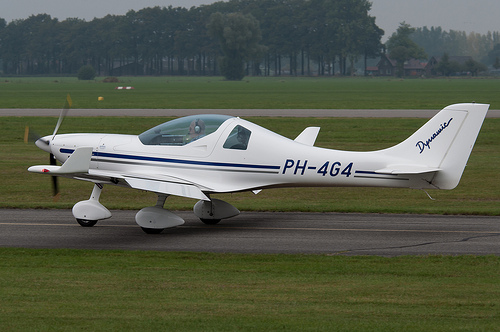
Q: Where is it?
A: This is at the airport.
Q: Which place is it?
A: It is an airport.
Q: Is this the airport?
A: Yes, it is the airport.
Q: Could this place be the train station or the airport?
A: It is the airport.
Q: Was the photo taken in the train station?
A: No, the picture was taken in the airport.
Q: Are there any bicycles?
A: No, there are no bicycles.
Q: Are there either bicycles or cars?
A: No, there are no bicycles or cars.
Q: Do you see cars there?
A: No, there are no cars.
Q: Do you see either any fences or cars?
A: No, there are no cars or fences.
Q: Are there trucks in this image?
A: No, there are no trucks.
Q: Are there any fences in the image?
A: No, there are no fences.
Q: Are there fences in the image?
A: No, there are no fences.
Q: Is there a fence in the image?
A: No, there are no fences.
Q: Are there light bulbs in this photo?
A: No, there are no light bulbs.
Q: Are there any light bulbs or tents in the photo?
A: No, there are no light bulbs or tents.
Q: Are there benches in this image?
A: No, there are no benches.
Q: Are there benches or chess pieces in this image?
A: No, there are no benches or chess pieces.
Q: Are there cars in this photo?
A: No, there are no cars.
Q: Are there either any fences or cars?
A: No, there are no cars or fences.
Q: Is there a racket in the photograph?
A: No, there are no rackets.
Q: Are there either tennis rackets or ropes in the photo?
A: No, there are no tennis rackets or ropes.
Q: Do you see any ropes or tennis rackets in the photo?
A: No, there are no tennis rackets or ropes.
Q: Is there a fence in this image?
A: No, there are no fences.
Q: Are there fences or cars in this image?
A: No, there are no fences or cars.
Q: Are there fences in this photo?
A: No, there are no fences.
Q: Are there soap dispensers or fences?
A: No, there are no fences or soap dispensers.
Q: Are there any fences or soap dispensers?
A: No, there are no fences or soap dispensers.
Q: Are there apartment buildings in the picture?
A: No, there are no apartment buildings.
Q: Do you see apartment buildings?
A: No, there are no apartment buildings.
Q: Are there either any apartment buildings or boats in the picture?
A: No, there are no apartment buildings or boats.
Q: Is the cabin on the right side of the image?
A: Yes, the cabin is on the right of the image.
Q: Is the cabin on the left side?
A: No, the cabin is on the right of the image.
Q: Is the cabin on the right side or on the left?
A: The cabin is on the right of the image.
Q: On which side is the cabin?
A: The cabin is on the right of the image.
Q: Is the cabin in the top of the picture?
A: Yes, the cabin is in the top of the image.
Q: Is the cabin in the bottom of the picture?
A: No, the cabin is in the top of the image.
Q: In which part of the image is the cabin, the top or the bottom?
A: The cabin is in the top of the image.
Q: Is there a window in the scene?
A: Yes, there is a window.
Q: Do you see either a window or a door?
A: Yes, there is a window.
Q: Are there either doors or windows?
A: Yes, there is a window.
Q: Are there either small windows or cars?
A: Yes, there is a small window.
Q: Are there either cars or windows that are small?
A: Yes, the window is small.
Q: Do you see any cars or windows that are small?
A: Yes, the window is small.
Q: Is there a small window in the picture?
A: Yes, there is a small window.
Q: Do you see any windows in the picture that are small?
A: Yes, there is a window that is small.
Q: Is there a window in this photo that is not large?
A: Yes, there is a small window.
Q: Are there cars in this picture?
A: No, there are no cars.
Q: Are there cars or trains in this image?
A: No, there are no cars or trains.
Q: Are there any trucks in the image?
A: No, there are no trucks.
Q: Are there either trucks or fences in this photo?
A: No, there are no trucks or fences.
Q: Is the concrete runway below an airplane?
A: Yes, the runway is below an airplane.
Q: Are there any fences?
A: No, there are no fences.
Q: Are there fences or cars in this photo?
A: No, there are no fences or cars.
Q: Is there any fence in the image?
A: No, there are no fences.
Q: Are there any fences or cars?
A: No, there are no fences or cars.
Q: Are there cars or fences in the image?
A: No, there are no fences or cars.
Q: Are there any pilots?
A: Yes, there is a pilot.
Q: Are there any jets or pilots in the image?
A: Yes, there is a pilot.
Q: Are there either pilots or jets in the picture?
A: Yes, there is a pilot.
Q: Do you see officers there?
A: No, there are no officers.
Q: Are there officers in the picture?
A: No, there are no officers.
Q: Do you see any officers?
A: No, there are no officers.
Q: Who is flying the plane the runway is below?
A: The pilot is flying the airplane.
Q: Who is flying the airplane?
A: The pilot is flying the airplane.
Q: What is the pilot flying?
A: The pilot is flying the plane.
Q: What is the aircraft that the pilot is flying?
A: The aircraft is an airplane.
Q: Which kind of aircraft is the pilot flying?
A: The pilot is flying the airplane.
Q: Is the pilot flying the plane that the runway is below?
A: Yes, the pilot is flying the airplane.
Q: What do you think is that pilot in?
A: The pilot is in the plane.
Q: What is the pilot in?
A: The pilot is in the plane.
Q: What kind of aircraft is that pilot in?
A: The pilot is in the airplane.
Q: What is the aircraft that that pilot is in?
A: The aircraft is an airplane.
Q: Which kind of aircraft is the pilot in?
A: The pilot is in the airplane.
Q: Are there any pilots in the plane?
A: Yes, there is a pilot in the plane.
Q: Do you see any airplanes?
A: Yes, there is an airplane.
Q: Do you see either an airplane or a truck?
A: Yes, there is an airplane.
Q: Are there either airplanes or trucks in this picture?
A: Yes, there is an airplane.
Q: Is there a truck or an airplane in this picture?
A: Yes, there is an airplane.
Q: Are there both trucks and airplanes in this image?
A: No, there is an airplane but no trucks.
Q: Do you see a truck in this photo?
A: No, there are no trucks.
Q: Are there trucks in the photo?
A: No, there are no trucks.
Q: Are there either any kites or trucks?
A: No, there are no trucks or kites.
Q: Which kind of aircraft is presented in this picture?
A: The aircraft is an airplane.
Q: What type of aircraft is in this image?
A: The aircraft is an airplane.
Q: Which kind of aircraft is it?
A: The aircraft is an airplane.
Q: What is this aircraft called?
A: This is an airplane.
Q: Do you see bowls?
A: No, there are no bowls.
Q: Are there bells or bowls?
A: No, there are no bowls or bells.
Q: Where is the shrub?
A: The shrub is on the grass.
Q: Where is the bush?
A: The shrub is on the grass.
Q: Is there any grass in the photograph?
A: Yes, there is grass.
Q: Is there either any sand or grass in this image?
A: Yes, there is grass.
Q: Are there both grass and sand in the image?
A: No, there is grass but no sand.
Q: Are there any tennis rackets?
A: No, there are no tennis rackets.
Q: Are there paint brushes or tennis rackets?
A: No, there are no tennis rackets or paint brushes.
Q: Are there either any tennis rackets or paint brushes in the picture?
A: No, there are no tennis rackets or paint brushes.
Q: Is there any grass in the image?
A: Yes, there is grass.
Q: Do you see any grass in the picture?
A: Yes, there is grass.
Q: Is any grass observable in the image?
A: Yes, there is grass.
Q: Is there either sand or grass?
A: Yes, there is grass.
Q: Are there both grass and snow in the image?
A: No, there is grass but no snow.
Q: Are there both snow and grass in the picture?
A: No, there is grass but no snow.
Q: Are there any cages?
A: No, there are no cages.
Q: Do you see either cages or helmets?
A: No, there are no cages or helmets.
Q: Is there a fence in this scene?
A: No, there are no fences.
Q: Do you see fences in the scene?
A: No, there are no fences.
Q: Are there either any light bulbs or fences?
A: No, there are no fences or light bulbs.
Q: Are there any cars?
A: No, there are no cars.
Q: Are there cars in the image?
A: No, there are no cars.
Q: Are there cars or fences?
A: No, there are no cars or fences.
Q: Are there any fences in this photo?
A: No, there are no fences.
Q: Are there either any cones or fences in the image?
A: No, there are no fences or cones.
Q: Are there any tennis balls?
A: No, there are no tennis balls.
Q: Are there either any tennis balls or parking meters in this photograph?
A: No, there are no tennis balls or parking meters.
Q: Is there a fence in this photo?
A: No, there are no fences.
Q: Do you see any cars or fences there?
A: No, there are no fences or cars.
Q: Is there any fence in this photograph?
A: No, there are no fences.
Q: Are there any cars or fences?
A: No, there are no fences or cars.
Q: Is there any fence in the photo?
A: No, there are no fences.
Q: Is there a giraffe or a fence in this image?
A: No, there are no fences or giraffes.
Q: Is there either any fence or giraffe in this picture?
A: No, there are no fences or giraffes.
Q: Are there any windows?
A: Yes, there is a window.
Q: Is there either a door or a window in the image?
A: Yes, there is a window.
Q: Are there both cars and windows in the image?
A: No, there is a window but no cars.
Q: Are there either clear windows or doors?
A: Yes, there is a clear window.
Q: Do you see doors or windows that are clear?
A: Yes, the window is clear.